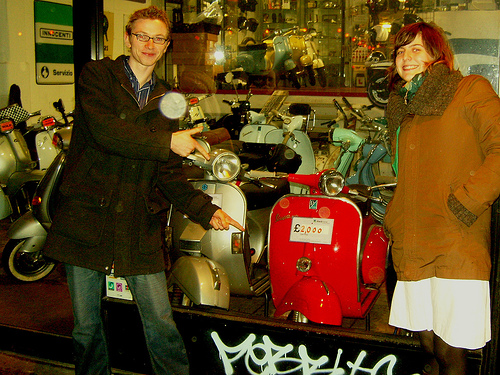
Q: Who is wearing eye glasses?
A: Man in black coat.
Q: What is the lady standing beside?
A: Red motor bike.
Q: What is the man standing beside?
A: A silver motor bike.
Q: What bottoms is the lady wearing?
A: A white skirt.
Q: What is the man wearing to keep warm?
A: A dark brown jacket.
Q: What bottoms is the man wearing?
A: Jeans.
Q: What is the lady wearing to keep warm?
A: A brown tan jacket.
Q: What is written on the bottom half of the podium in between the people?
A: Graffiti.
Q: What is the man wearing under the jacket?
A: A blue shirt.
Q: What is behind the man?
A: Motor bikes.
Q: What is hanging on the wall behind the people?
A: A mirror.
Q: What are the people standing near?
A: Scooters.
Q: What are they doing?
A: Pointing at a machine.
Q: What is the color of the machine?
A: Red.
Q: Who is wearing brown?
A: The woman.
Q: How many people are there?
A: 2.